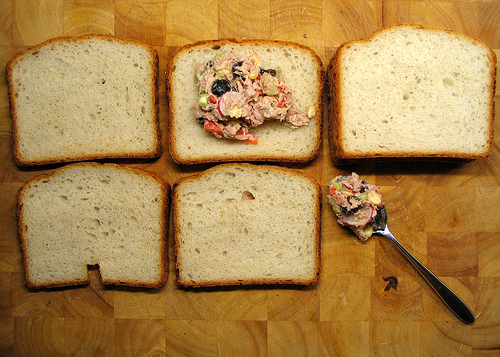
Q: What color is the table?
A: Brown.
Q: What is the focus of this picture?
A: Bread.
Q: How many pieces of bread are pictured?
A: Five.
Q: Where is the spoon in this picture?
A: Bottom Right.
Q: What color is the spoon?
A: Silver.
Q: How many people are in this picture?
A: Zero.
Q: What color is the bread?
A: White.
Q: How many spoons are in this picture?
A: One.